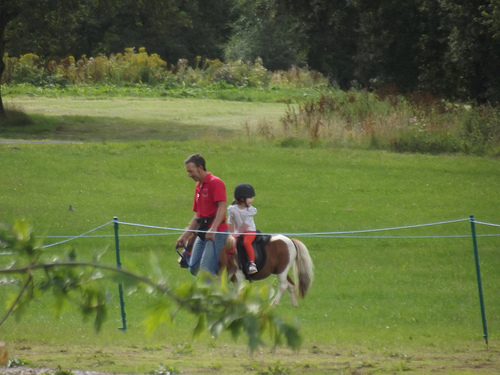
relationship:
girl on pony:
[226, 183, 258, 274] [195, 226, 322, 326]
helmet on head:
[228, 175, 260, 200] [228, 179, 258, 209]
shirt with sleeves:
[192, 180, 221, 217] [208, 173, 228, 200]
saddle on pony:
[239, 235, 268, 275] [204, 226, 320, 316]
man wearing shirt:
[174, 154, 228, 314] [193, 171, 228, 216]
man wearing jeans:
[174, 151, 226, 320] [193, 226, 225, 300]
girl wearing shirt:
[226, 183, 258, 274] [223, 200, 260, 231]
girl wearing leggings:
[226, 183, 258, 274] [223, 226, 269, 276]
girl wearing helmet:
[222, 174, 269, 269] [232, 180, 261, 206]